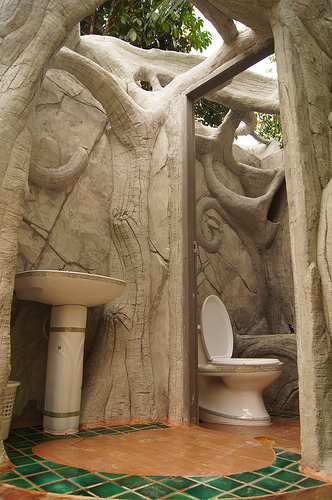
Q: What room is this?
A: It is a bathroom.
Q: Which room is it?
A: It is a bathroom.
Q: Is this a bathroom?
A: Yes, it is a bathroom.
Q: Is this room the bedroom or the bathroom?
A: It is the bathroom.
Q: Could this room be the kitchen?
A: No, it is the bathroom.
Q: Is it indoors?
A: Yes, it is indoors.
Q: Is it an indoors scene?
A: Yes, it is indoors.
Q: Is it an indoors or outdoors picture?
A: It is indoors.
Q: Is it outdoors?
A: No, it is indoors.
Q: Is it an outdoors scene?
A: No, it is indoors.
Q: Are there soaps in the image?
A: No, there are no soaps.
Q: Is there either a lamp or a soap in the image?
A: No, there are no soaps or lamps.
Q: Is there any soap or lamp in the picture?
A: No, there are no soaps or lamps.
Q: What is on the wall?
A: The trunk is on the wall.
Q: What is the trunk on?
A: The trunk is on the wall.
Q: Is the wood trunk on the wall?
A: Yes, the trunk is on the wall.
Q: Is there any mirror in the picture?
A: No, there are no mirrors.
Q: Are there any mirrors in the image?
A: No, there are no mirrors.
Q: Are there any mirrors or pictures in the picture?
A: No, there are no mirrors or pictures.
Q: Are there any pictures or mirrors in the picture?
A: No, there are no mirrors or pictures.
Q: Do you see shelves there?
A: No, there are no shelves.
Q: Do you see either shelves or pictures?
A: No, there are no shelves or pictures.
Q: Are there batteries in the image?
A: No, there are no batteries.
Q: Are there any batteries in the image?
A: No, there are no batteries.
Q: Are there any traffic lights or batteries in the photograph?
A: No, there are no batteries or traffic lights.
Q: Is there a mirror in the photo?
A: No, there are no mirrors.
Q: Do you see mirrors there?
A: No, there are no mirrors.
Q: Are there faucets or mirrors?
A: No, there are no mirrors or faucets.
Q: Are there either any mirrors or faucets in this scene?
A: No, there are no mirrors or faucets.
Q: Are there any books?
A: No, there are no books.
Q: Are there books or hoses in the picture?
A: No, there are no books or hoses.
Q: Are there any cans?
A: No, there are no cans.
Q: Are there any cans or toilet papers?
A: No, there are no cans or toilet papers.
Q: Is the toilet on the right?
A: Yes, the toilet is on the right of the image.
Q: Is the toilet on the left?
A: No, the toilet is on the right of the image.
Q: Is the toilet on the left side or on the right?
A: The toilet is on the right of the image.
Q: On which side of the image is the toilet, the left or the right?
A: The toilet is on the right of the image.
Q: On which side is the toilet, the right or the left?
A: The toilet is on the right of the image.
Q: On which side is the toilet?
A: The toilet is on the right of the image.